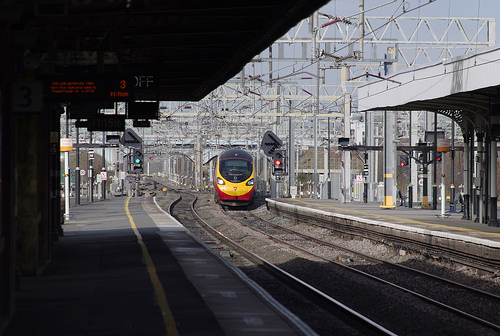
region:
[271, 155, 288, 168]
Red traffic train light.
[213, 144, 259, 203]
Yellow and red train.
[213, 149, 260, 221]
Train arriving on tracks.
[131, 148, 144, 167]
Green go light for train.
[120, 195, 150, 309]
Yellow thick line on pavement.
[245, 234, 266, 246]
Brown dirt between tracks.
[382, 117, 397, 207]
Yellow paint on gray post.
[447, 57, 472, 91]
Shadow from steel bars above.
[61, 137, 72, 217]
Yellow and white sign on post.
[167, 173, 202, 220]
Track with no train.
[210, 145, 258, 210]
a black, red, and yellow train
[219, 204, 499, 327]
a set of train tracks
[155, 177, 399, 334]
a set of train tracks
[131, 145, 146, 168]
A train station traffic light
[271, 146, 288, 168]
A train station traffic light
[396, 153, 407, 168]
A train station traffic light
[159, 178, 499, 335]
some gravel on a track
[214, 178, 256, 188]
a pair of headlights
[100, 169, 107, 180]
a red and white sign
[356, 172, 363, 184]
a red and white sign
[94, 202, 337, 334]
shade of the building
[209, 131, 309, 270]
train is moving on the rail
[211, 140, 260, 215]
the train is on trucks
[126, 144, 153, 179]
lights are green in color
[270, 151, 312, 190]
lights are red i n color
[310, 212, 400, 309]
the railis made of rocks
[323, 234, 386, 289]
railway is grayin color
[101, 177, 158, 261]
the road has a yellow lane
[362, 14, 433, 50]
th sky is dullin cl=olor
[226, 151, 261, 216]
train is yellow and red in coor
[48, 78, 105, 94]
orange words on sign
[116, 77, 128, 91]
orange # on sign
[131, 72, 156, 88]
white letters on sign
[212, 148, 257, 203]
train is yellow and red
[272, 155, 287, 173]
red light on stoplight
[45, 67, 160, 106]
signs hanging from ceiling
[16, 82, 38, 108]
black number on sign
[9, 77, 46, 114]
the sign is white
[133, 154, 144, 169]
green light on stop light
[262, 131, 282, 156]
black arrow on sign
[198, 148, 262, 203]
red and yellow train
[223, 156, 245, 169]
front window of train cab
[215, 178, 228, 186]
front light of train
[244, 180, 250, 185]
front light of train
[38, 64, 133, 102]
digital sign hanging on wall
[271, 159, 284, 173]
red light is lit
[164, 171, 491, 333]
metal train tracks at station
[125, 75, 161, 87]
sign with white lettering